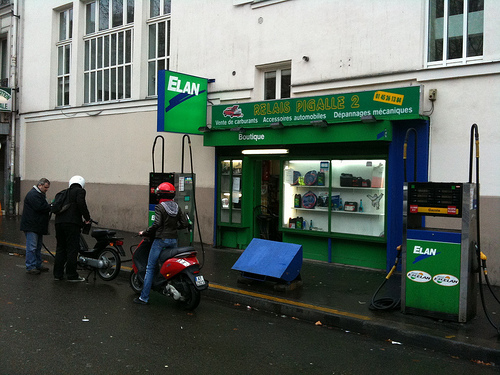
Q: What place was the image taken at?
A: It was taken at the sidewalk.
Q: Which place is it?
A: It is a sidewalk.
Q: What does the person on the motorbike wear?
A: The person wears a helmet.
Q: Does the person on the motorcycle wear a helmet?
A: Yes, the person wears a helmet.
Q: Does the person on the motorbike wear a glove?
A: No, the person wears a helmet.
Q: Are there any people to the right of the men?
A: Yes, there is a person to the right of the men.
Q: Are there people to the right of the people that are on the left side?
A: Yes, there is a person to the right of the men.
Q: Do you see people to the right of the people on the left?
A: Yes, there is a person to the right of the men.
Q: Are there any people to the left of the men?
A: No, the person is to the right of the men.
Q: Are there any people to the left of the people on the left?
A: No, the person is to the right of the men.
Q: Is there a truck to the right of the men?
A: No, there is a person to the right of the men.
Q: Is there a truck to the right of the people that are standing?
A: No, there is a person to the right of the men.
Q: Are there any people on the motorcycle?
A: Yes, there is a person on the motorcycle.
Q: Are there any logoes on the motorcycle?
A: No, there is a person on the motorcycle.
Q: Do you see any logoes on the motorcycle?
A: No, there is a person on the motorcycle.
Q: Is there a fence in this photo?
A: No, there are no fences.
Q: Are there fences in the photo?
A: No, there are no fences.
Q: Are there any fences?
A: No, there are no fences.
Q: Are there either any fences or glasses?
A: No, there are no fences or glasses.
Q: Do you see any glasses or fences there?
A: No, there are no fences or glasses.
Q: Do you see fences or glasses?
A: No, there are no fences or glasses.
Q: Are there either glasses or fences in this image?
A: No, there are no fences or glasses.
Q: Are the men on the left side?
A: Yes, the men are on the left of the image.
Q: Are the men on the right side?
A: No, the men are on the left of the image.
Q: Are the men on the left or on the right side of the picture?
A: The men are on the left of the image.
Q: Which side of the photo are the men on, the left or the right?
A: The men are on the left of the image.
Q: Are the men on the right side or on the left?
A: The men are on the left of the image.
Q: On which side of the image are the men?
A: The men are on the left of the image.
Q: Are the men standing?
A: Yes, the men are standing.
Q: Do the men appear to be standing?
A: Yes, the men are standing.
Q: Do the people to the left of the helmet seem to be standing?
A: Yes, the men are standing.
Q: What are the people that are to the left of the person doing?
A: The men are standing.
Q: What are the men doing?
A: The men are standing.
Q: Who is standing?
A: The men are standing.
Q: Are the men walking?
A: No, the men are standing.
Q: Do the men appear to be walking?
A: No, the men are standing.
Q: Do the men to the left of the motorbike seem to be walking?
A: No, the men are standing.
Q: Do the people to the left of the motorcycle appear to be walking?
A: No, the men are standing.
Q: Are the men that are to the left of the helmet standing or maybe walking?
A: The men are standing.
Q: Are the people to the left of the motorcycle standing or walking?
A: The men are standing.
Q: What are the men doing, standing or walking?
A: The men are standing.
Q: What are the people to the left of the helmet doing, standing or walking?
A: The men are standing.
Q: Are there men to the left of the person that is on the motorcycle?
A: Yes, there are men to the left of the person.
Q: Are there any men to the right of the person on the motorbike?
A: No, the men are to the left of the person.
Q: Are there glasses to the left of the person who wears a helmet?
A: No, there are men to the left of the person.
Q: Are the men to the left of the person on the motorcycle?
A: Yes, the men are to the left of the person.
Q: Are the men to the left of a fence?
A: No, the men are to the left of the person.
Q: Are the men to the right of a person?
A: No, the men are to the left of a person.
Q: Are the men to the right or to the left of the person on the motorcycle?
A: The men are to the left of the person.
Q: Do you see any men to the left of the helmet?
A: Yes, there are men to the left of the helmet.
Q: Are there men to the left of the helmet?
A: Yes, there are men to the left of the helmet.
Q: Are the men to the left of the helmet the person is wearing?
A: Yes, the men are to the left of the helmet.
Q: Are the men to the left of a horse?
A: No, the men are to the left of the helmet.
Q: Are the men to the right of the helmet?
A: No, the men are to the left of the helmet.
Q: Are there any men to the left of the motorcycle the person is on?
A: Yes, there are men to the left of the motorcycle.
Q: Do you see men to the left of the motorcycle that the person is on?
A: Yes, there are men to the left of the motorcycle.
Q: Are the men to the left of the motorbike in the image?
A: Yes, the men are to the left of the motorbike.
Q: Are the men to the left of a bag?
A: No, the men are to the left of the motorbike.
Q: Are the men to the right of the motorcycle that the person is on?
A: No, the men are to the left of the motorbike.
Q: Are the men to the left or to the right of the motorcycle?
A: The men are to the left of the motorcycle.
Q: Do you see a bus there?
A: No, there are no buses.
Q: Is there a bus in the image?
A: No, there are no buses.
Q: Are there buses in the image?
A: No, there are no buses.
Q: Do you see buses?
A: No, there are no buses.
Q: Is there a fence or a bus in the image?
A: No, there are no buses or fences.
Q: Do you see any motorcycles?
A: Yes, there is a motorcycle.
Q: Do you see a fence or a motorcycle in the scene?
A: Yes, there is a motorcycle.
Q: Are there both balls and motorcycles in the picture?
A: No, there is a motorcycle but no balls.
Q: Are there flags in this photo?
A: No, there are no flags.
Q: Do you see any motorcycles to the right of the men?
A: Yes, there is a motorcycle to the right of the men.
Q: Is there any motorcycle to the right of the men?
A: Yes, there is a motorcycle to the right of the men.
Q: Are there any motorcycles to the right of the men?
A: Yes, there is a motorcycle to the right of the men.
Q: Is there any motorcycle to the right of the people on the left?
A: Yes, there is a motorcycle to the right of the men.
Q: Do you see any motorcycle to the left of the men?
A: No, the motorcycle is to the right of the men.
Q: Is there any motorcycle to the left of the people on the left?
A: No, the motorcycle is to the right of the men.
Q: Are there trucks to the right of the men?
A: No, there is a motorcycle to the right of the men.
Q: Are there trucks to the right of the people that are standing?
A: No, there is a motorcycle to the right of the men.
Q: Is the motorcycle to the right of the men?
A: Yes, the motorcycle is to the right of the men.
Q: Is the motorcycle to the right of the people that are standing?
A: Yes, the motorcycle is to the right of the men.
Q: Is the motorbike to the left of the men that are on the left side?
A: No, the motorbike is to the right of the men.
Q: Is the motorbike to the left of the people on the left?
A: No, the motorbike is to the right of the men.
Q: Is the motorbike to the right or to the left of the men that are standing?
A: The motorbike is to the right of the men.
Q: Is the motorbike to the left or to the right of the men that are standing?
A: The motorbike is to the right of the men.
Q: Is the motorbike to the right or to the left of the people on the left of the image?
A: The motorbike is to the right of the men.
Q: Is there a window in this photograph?
A: Yes, there is a window.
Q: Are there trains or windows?
A: Yes, there is a window.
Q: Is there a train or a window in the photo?
A: Yes, there is a window.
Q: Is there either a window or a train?
A: Yes, there is a window.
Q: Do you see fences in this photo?
A: No, there are no fences.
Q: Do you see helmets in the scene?
A: Yes, there is a helmet.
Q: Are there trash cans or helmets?
A: Yes, there is a helmet.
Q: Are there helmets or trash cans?
A: Yes, there is a helmet.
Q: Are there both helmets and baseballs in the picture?
A: No, there is a helmet but no baseballs.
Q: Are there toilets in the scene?
A: No, there are no toilets.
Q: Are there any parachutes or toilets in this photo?
A: No, there are no toilets or parachutes.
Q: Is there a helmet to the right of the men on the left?
A: Yes, there is a helmet to the right of the men.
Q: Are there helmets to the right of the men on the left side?
A: Yes, there is a helmet to the right of the men.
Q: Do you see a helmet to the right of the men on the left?
A: Yes, there is a helmet to the right of the men.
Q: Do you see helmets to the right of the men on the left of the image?
A: Yes, there is a helmet to the right of the men.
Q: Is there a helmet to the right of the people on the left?
A: Yes, there is a helmet to the right of the men.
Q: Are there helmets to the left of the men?
A: No, the helmet is to the right of the men.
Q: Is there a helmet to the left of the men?
A: No, the helmet is to the right of the men.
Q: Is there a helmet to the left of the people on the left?
A: No, the helmet is to the right of the men.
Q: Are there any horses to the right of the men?
A: No, there is a helmet to the right of the men.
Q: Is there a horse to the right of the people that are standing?
A: No, there is a helmet to the right of the men.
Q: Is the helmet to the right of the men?
A: Yes, the helmet is to the right of the men.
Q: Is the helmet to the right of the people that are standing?
A: Yes, the helmet is to the right of the men.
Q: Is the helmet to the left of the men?
A: No, the helmet is to the right of the men.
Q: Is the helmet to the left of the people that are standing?
A: No, the helmet is to the right of the men.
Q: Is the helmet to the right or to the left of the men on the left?
A: The helmet is to the right of the men.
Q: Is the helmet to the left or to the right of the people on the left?
A: The helmet is to the right of the men.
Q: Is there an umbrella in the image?
A: No, there are no umbrellas.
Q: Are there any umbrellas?
A: No, there are no umbrellas.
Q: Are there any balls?
A: No, there are no balls.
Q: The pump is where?
A: The pump is on the sidewalk.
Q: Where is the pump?
A: The pump is on the sidewalk.